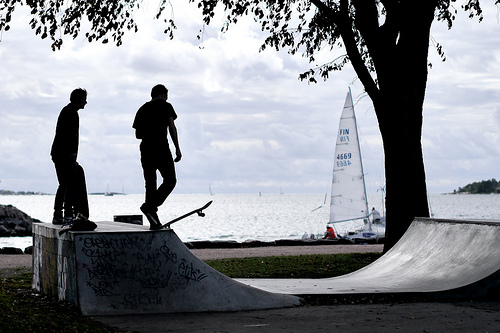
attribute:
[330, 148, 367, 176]
numbers — id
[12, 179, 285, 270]
sailboat — white 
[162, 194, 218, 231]
skateboard — small, black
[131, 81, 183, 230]
man — skating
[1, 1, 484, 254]
tree — very dark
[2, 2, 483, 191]
sky — overcast, cloudy, blue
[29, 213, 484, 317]
skate ramp — cement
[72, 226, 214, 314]
graffiti — random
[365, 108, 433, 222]
trunk — thick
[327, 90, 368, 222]
sail — white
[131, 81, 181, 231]
guy — skateboarding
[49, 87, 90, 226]
guy — skateboarding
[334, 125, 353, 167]
writing — black